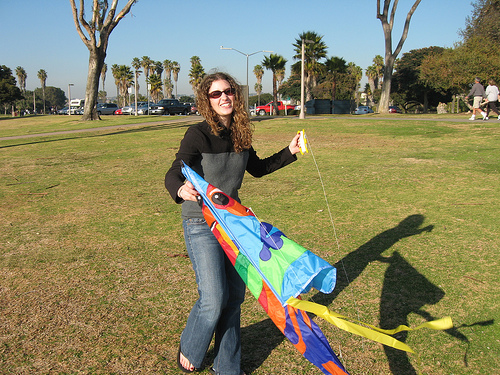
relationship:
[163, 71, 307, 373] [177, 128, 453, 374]
woman holding kite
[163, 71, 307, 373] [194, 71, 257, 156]
woman curly hair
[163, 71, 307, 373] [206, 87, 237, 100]
woman wearing sunglasses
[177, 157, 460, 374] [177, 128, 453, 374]
brightly colored kite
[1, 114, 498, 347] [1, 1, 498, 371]
grass large park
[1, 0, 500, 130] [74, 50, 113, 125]
trees and trunks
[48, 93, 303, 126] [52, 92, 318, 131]
full parking lot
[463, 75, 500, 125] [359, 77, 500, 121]
two on walking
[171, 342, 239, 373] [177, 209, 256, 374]
sandals with jeans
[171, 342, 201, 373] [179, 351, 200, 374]
sandals on foot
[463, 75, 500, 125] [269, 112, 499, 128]
two walking path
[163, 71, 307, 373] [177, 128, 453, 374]
woman and kite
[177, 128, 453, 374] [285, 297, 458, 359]
kite yellow tail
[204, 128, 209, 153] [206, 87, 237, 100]
black frames sunglasses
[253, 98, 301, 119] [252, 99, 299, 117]
parked red truck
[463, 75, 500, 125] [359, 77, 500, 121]
two people walking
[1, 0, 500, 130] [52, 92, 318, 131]
trees lining lot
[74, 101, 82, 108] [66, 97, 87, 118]
white camper truck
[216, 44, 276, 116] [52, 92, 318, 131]
poles in lot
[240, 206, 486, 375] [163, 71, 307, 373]
shadow of woman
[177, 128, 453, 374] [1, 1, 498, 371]
kite in park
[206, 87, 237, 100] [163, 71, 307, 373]
sunglasses on woman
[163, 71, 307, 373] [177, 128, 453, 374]
woman with kite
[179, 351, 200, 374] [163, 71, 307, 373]
foot of woman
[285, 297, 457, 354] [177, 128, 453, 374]
tail on kite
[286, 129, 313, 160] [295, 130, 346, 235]
hand holding string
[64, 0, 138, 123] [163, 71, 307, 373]
trees behind woman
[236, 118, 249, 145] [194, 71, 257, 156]
brown wavy hair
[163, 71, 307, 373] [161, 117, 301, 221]
woman in top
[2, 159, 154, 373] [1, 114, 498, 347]
browish large grass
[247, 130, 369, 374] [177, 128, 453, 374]
string to kite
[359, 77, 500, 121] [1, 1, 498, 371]
walking in park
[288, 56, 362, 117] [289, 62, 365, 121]
tree with leaves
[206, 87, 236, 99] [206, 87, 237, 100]
sunglasses of sunglasses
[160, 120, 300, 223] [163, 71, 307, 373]
sweater on woman